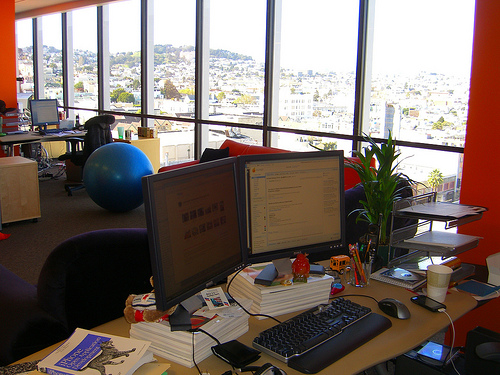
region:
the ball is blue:
[83, 139, 155, 219]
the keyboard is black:
[266, 308, 394, 368]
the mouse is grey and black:
[378, 291, 419, 323]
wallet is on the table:
[210, 329, 267, 369]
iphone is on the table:
[410, 290, 446, 311]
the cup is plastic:
[422, 263, 457, 298]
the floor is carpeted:
[37, 197, 104, 239]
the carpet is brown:
[24, 214, 80, 243]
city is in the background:
[74, 27, 427, 134]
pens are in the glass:
[344, 246, 377, 286]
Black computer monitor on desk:
[140, 156, 248, 331]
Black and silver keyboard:
[252, 295, 372, 361]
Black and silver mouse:
[376, 296, 411, 321]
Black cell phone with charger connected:
[409, 292, 448, 314]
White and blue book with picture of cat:
[36, 326, 155, 374]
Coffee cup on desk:
[423, 263, 452, 307]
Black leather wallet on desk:
[209, 336, 261, 368]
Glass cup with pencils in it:
[344, 238, 376, 288]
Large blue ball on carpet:
[82, 141, 154, 214]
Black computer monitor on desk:
[27, 98, 60, 135]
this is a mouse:
[375, 288, 414, 325]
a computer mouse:
[373, 291, 412, 323]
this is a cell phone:
[398, 285, 444, 315]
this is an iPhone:
[409, 289, 450, 311]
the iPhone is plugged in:
[402, 286, 459, 338]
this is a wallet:
[207, 337, 259, 370]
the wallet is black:
[203, 339, 260, 373]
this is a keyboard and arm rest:
[250, 290, 397, 372]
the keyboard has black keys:
[244, 287, 369, 367]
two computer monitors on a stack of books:
[124, 144, 367, 321]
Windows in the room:
[15, 1, 475, 233]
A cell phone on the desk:
[413, 294, 444, 312]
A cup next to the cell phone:
[426, 264, 451, 301]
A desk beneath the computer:
[3, 261, 475, 373]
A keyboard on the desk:
[253, 299, 369, 364]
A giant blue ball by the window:
[83, 141, 153, 209]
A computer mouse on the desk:
[376, 295, 408, 312]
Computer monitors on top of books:
[141, 150, 343, 309]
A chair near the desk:
[59, 113, 113, 200]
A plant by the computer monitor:
[343, 130, 401, 240]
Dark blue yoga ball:
[80, 138, 156, 218]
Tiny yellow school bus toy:
[326, 252, 355, 277]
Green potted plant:
[341, 129, 426, 270]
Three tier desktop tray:
[387, 189, 488, 284]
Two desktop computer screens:
[137, 148, 352, 314]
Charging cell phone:
[407, 293, 462, 374]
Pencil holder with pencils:
[344, 237, 376, 289]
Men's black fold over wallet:
[209, 338, 263, 370]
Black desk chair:
[55, 112, 116, 198]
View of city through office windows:
[12, 0, 473, 199]